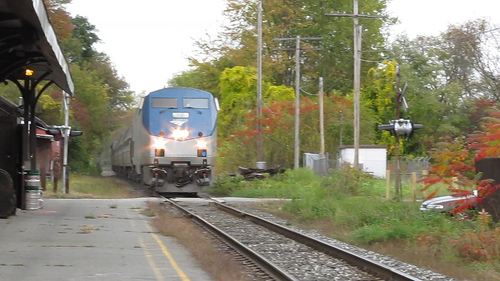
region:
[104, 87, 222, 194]
a train with a blue front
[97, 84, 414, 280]
a train on the tracks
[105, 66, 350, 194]
a train beside trees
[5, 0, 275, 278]
a train pulling into the station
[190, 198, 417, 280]
train tracks beside grass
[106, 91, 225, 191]
a train with its lights on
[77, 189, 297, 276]
concrete beside train tracks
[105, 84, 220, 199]
A train travelling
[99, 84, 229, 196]
a train headed straight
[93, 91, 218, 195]
a train facing forward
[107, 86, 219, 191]
Amtrak train coming down the track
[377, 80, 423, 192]
railroad crossing sign on the rigt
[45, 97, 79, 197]
railroad crossing sign on the left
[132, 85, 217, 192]
the train's engine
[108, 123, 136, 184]
passenger cars behind the engine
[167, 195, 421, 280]
train track beside the platform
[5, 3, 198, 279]
a train platform on the left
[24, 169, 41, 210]
metal keg barrels on the platform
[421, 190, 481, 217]
front of a car parked in the grass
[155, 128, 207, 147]
front headlights of the train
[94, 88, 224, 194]
a train on the tracks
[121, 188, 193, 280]
yellow lines on the road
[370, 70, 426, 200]
a light before the train track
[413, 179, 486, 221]
a car parked beside the road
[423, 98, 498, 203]
the leaves are red and yellow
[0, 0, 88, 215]
a train station beside the track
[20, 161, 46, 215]
a bottle beside the track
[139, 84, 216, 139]
the train front is blue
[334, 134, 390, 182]
a shed across the street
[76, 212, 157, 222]
grass growing in the cracks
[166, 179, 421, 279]
train tracks with rocks in middle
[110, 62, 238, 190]
blue and grey train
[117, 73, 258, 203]
train with headlights on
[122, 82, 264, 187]
train with lights on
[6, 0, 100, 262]
front of train station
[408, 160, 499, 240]
car parked in field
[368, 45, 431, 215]
sign for railroad crossing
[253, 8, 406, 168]
electric line poles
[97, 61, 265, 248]
train pulling into the station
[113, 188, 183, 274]
yellow line to stop people from standing close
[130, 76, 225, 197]
train engine with headlights on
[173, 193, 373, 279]
train tracks next to grass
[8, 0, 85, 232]
building overhang with silver cylinder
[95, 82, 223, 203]
oncoming train with headlights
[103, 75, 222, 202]
train with blue engine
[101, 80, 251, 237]
train running on train tracks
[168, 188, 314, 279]
train tracks with gravel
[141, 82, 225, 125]
front windows of train engine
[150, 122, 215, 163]
three headlights on train engine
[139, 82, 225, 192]
front of train engine with headlights on